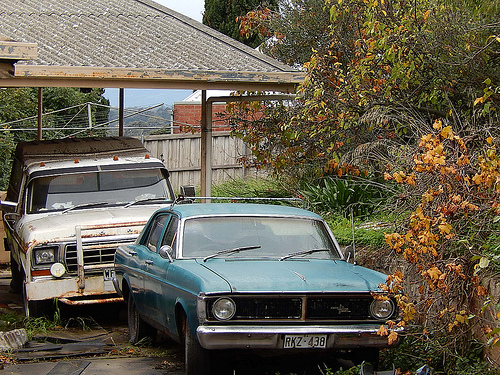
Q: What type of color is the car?
A: Blue.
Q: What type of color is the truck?
A: White.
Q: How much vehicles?
A: 2.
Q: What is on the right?
A: Trees.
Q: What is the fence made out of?
A: Wood.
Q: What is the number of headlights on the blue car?
A: Two.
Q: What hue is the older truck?
A: White.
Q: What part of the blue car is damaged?
A: Front grill.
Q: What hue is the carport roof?
A: Grey.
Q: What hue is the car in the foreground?
A: Blue.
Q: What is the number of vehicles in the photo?
A: Two.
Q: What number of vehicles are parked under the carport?
A: One.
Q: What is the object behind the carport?
A: Wooden fence.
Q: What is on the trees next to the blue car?
A: Dying leaves.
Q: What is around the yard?
A: A fence.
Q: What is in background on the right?
A: Trees.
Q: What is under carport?
A: White truck.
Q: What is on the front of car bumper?
A: A tag.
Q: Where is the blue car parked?
A: In front of truck.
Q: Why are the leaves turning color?
A: Autumn.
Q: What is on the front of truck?
A: Brackets.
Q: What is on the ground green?
A: Grass.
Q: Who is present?
A: No one.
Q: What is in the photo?
A: Plants.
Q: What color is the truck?
A: White.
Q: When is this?
A: Daytime.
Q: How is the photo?
A: Clear.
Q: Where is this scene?
A: Near junk cars.